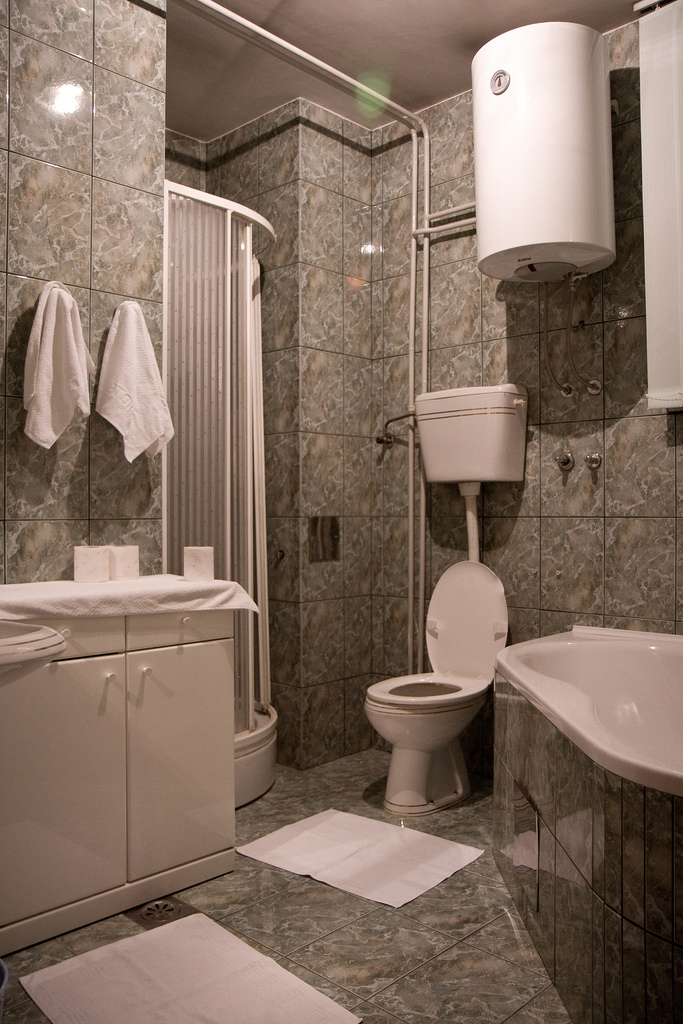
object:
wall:
[301, 98, 377, 768]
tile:
[344, 353, 374, 438]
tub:
[492, 621, 683, 793]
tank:
[467, 17, 618, 290]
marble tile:
[304, 265, 432, 404]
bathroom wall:
[301, 101, 516, 548]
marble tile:
[297, 98, 469, 638]